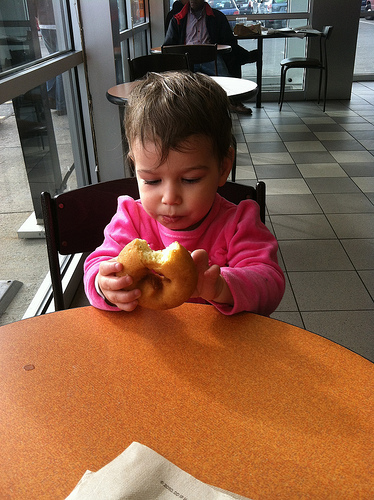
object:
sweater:
[82, 190, 285, 319]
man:
[163, 0, 255, 118]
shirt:
[184, 8, 209, 46]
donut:
[115, 238, 199, 313]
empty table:
[106, 76, 260, 108]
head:
[123, 70, 239, 228]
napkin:
[62, 441, 248, 500]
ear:
[218, 145, 234, 187]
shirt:
[82, 191, 286, 315]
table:
[0, 301, 374, 433]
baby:
[83, 70, 287, 315]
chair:
[40, 178, 267, 312]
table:
[104, 73, 260, 106]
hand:
[97, 260, 142, 311]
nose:
[161, 174, 182, 206]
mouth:
[159, 212, 188, 223]